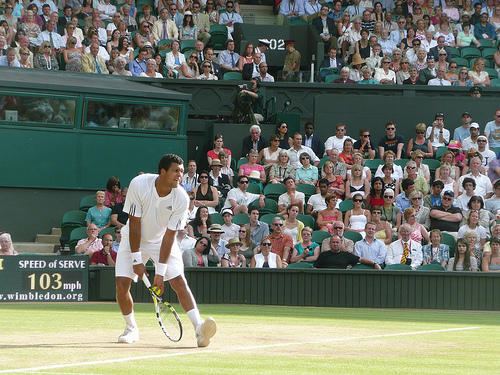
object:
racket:
[141, 273, 182, 342]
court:
[0, 301, 500, 375]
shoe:
[195, 317, 216, 348]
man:
[115, 153, 217, 347]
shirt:
[313, 249, 360, 269]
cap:
[207, 223, 225, 234]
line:
[1, 325, 478, 374]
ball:
[152, 286, 161, 296]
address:
[0, 292, 83, 302]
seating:
[0, 0, 500, 271]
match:
[0, 0, 500, 374]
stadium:
[0, 68, 193, 192]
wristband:
[131, 251, 143, 265]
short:
[114, 237, 184, 283]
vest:
[348, 209, 367, 238]